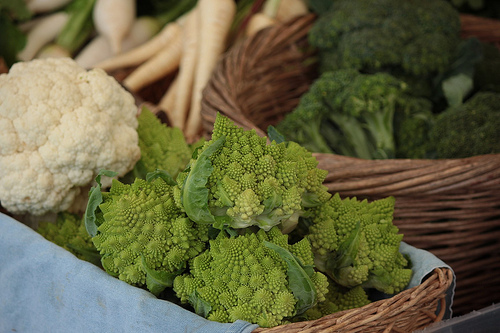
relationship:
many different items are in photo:
[2, 0, 498, 329] [0, 0, 500, 332]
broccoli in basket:
[270, 2, 500, 158] [1, 60, 457, 331]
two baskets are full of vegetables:
[2, 1, 499, 332] [0, 1, 500, 328]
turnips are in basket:
[4, 0, 307, 137] [4, 1, 280, 146]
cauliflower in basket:
[0, 54, 147, 215] [1, 60, 457, 331]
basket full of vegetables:
[1, 60, 457, 331] [0, 1, 500, 328]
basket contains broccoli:
[1, 60, 457, 331] [270, 2, 500, 158]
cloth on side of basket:
[0, 212, 459, 332] [1, 60, 457, 331]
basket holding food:
[1, 60, 457, 331] [270, 2, 500, 158]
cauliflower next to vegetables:
[0, 54, 147, 215] [35, 110, 417, 331]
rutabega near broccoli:
[0, 1, 309, 144] [270, 2, 500, 158]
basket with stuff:
[1, 60, 457, 331] [171, 110, 331, 232]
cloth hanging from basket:
[0, 212, 459, 332] [1, 60, 457, 331]